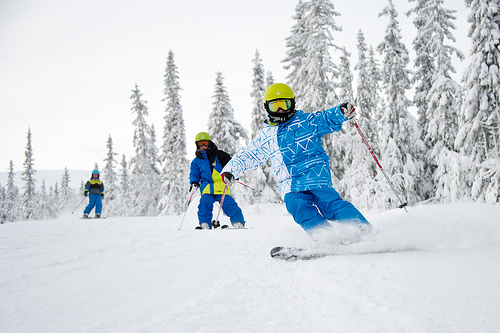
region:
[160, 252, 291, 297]
part of white snow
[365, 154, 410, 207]
part of a hooker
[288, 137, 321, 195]
part of a white jacket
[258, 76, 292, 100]
part of a yellow helmet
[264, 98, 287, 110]
part of a sunglass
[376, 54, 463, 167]
part of white snow trees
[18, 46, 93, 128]
part of the white sky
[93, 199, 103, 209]
part of a blue track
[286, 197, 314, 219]
right leg of the skater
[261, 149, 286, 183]
white part of a jacket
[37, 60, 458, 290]
Three people are skiing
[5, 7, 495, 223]
the trees are snow covered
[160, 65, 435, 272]
two skiers are wearing yellow helmets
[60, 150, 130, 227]
the skier is wearing a blue helmet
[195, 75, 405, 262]
the skier is wearing a blue and white jacket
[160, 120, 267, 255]
the skier is wearing a blue and yellow jacket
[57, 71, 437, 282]
the skiers are wearing blue pants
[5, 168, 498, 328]
the snow is white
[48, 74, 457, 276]
the skiers are carrying ski poles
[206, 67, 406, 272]
the skier is wearing goggles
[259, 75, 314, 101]
the helmet is yellow green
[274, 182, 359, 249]
the pants are blue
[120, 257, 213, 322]
the snow is white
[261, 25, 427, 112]
trees are covered in snow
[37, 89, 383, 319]
three kids skiing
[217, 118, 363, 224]
jacket is blue and white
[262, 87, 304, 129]
a kid wearing goggles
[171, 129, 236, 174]
a kid wearing helmet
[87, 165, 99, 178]
the helmet is blue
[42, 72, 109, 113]
the sky is white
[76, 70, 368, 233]
Three people wearing blue and yellow snow gear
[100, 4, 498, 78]
Row of snow covered trees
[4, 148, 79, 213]
View of hill behind row of snow covered trees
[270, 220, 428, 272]
Black snow skis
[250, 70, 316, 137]
Yellow helmet and ski goggles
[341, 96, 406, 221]
Red ski stick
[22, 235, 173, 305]
Snow covered hill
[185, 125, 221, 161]
Person wearing yellow helmet and red ski goggles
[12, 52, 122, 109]
Clear grayish white sky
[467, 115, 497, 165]
Broken snow covered branches hanging on tree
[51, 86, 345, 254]
these are three boys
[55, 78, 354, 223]
the boys are snow skating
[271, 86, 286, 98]
the boy is wearing a hemet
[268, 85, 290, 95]
the helmet is yellow in color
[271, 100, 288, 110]
the boy is having yellow goggles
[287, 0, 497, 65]
the trees are full of snow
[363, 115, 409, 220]
the boy is holding a pole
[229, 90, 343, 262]
the boy is slanted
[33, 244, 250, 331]
the place is full of snow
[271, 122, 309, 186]
the jacket is blue and white in color